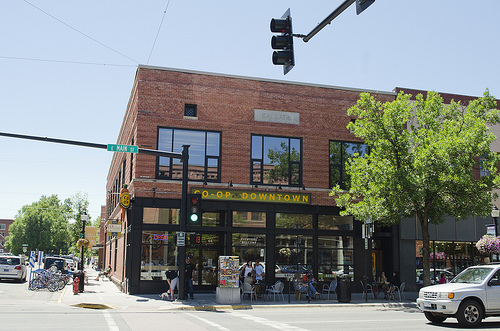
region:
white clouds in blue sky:
[55, 25, 80, 58]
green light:
[179, 194, 199, 225]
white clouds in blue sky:
[40, 60, 72, 90]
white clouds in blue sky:
[164, 20, 181, 45]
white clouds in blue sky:
[210, 22, 239, 54]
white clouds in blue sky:
[29, 40, 61, 72]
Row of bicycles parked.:
[23, 245, 77, 302]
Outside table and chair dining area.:
[225, 250, 366, 310]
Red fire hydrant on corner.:
[53, 262, 101, 308]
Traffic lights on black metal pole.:
[217, 0, 372, 97]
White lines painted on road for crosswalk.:
[88, 273, 305, 328]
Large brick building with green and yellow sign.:
[115, 165, 405, 319]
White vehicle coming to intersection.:
[416, 242, 498, 329]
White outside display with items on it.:
[206, 243, 257, 306]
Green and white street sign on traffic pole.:
[79, 132, 167, 164]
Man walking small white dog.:
[130, 250, 195, 310]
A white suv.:
[415, 265, 498, 325]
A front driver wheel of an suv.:
[456, 298, 485, 328]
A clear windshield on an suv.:
[451, 266, 493, 287]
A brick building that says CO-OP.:
[98, 62, 398, 302]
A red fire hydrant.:
[70, 274, 80, 294]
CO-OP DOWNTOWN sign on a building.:
[188, 187, 311, 207]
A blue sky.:
[0, 0, 497, 205]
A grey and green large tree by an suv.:
[327, 92, 499, 286]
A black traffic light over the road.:
[270, 9, 295, 73]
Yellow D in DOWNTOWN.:
[240, 190, 247, 200]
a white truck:
[418, 263, 499, 329]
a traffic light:
[265, 0, 375, 80]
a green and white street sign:
[102, 142, 142, 154]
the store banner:
[191, 183, 314, 210]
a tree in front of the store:
[325, 83, 498, 295]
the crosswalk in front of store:
[98, 305, 297, 330]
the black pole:
[178, 139, 194, 301]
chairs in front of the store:
[265, 263, 407, 300]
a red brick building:
[97, 63, 497, 296]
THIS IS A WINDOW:
[152, 128, 222, 179]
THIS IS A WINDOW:
[251, 139, 304, 180]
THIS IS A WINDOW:
[145, 208, 183, 230]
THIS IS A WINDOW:
[189, 211, 231, 228]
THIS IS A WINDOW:
[225, 205, 267, 227]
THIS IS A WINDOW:
[314, 214, 357, 229]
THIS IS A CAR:
[420, 262, 499, 324]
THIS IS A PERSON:
[299, 266, 319, 299]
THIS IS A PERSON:
[163, 260, 184, 292]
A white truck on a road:
[415, 263, 499, 318]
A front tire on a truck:
[457, 295, 482, 325]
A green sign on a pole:
[101, 141, 138, 153]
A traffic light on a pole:
[269, 13, 294, 73]